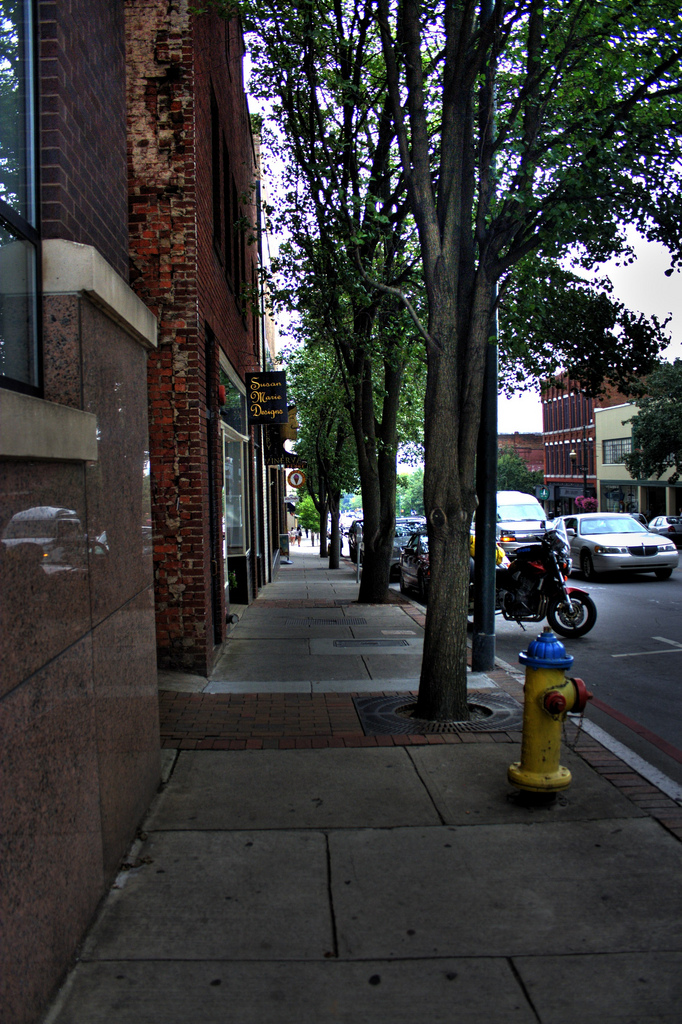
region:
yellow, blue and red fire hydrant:
[501, 621, 596, 804]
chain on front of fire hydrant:
[555, 703, 587, 751]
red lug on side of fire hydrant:
[536, 687, 571, 724]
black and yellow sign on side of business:
[238, 364, 294, 431]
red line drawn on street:
[588, 691, 680, 778]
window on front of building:
[0, 0, 55, 406]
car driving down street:
[546, 508, 681, 588]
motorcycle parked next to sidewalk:
[471, 515, 602, 643]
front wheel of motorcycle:
[541, 583, 600, 646]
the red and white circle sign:
[285, 468, 302, 484]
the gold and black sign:
[244, 367, 287, 417]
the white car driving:
[550, 509, 677, 579]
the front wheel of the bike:
[550, 585, 600, 635]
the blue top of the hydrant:
[521, 628, 570, 668]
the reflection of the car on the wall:
[34, 521, 114, 591]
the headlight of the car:
[600, 542, 628, 555]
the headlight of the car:
[652, 540, 677, 553]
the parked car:
[646, 511, 680, 538]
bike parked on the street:
[428, 519, 593, 645]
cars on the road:
[470, 470, 673, 579]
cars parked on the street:
[348, 508, 513, 613]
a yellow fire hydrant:
[508, 612, 591, 810]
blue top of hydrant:
[512, 612, 574, 672]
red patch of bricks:
[178, 670, 473, 771]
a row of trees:
[233, 2, 680, 758]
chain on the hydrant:
[547, 697, 586, 755]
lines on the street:
[601, 601, 676, 696]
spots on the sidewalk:
[136, 760, 544, 1000]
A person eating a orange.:
[399, 749, 457, 879]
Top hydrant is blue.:
[526, 621, 567, 680]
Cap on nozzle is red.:
[547, 693, 565, 715]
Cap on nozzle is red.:
[571, 674, 598, 719]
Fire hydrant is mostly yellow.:
[510, 641, 575, 800]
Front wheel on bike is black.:
[549, 585, 609, 636]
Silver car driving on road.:
[551, 495, 677, 589]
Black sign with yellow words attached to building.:
[245, 370, 286, 428]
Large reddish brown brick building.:
[139, 133, 256, 643]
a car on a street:
[549, 495, 680, 581]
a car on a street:
[643, 512, 680, 538]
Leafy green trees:
[234, 4, 680, 600]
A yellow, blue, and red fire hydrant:
[514, 619, 584, 802]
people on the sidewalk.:
[287, 524, 315, 550]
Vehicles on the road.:
[376, 479, 667, 657]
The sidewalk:
[55, 521, 667, 1022]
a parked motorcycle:
[467, 524, 609, 665]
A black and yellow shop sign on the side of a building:
[245, 369, 286, 421]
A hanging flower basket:
[573, 493, 607, 514]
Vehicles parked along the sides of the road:
[332, 492, 587, 667]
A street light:
[561, 446, 596, 511]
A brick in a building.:
[182, 520, 198, 528]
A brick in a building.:
[166, 485, 180, 494]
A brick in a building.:
[150, 454, 168, 466]